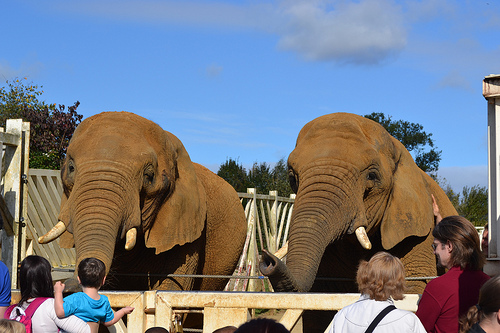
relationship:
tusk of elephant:
[123, 226, 136, 252] [39, 107, 249, 296]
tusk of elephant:
[31, 221, 66, 243] [39, 107, 249, 296]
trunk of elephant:
[238, 47, 359, 314] [288, 113, 426, 271]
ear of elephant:
[145, 148, 207, 254] [252, 109, 465, 291]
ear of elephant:
[380, 135, 433, 251] [39, 107, 249, 296]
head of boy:
[17, 254, 54, 294] [52, 256, 135, 328]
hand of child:
[116, 296, 153, 311] [62, 259, 131, 317]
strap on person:
[360, 302, 394, 331] [320, 249, 433, 331]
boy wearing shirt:
[54, 258, 135, 330] [63, 293, 114, 320]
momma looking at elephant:
[4, 255, 101, 331] [252, 109, 465, 291]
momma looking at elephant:
[4, 255, 101, 331] [39, 107, 249, 296]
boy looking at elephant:
[52, 256, 135, 328] [252, 109, 465, 291]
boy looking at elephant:
[52, 256, 135, 328] [39, 107, 249, 296]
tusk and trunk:
[123, 226, 139, 252] [74, 195, 121, 285]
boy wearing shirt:
[52, 256, 135, 328] [65, 287, 120, 317]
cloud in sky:
[259, 4, 439, 97] [2, 0, 492, 182]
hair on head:
[362, 259, 397, 294] [10, 242, 45, 292]